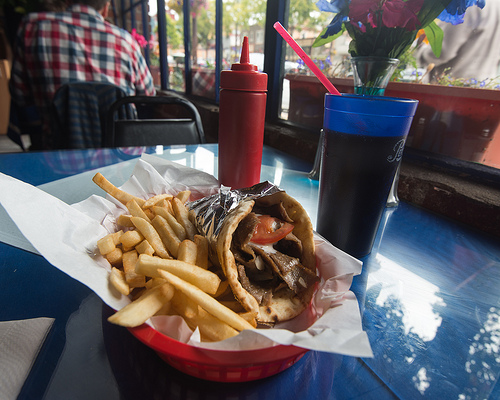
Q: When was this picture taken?
A: During the day.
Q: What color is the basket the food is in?
A: Red.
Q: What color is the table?
A: Blue.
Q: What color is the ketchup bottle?
A: Red.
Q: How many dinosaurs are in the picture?
A: Zero.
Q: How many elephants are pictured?
A: Zero.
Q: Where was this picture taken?
A: At a cafe.